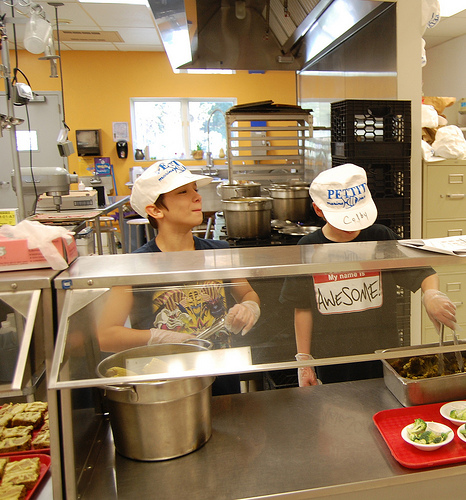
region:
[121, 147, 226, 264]
woman wears a white cap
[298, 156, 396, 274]
woman wears a white cap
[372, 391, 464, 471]
a red tray on a counter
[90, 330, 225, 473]
a pot color silver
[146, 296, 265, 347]
a pair of gloves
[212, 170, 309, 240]
pots over a stove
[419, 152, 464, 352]
a cabinet color beige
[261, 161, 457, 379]
woman wears a black top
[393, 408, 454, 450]
a white bowl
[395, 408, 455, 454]
a bowl with broccoli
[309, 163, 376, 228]
a white cap of the business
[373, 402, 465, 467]
a red cafeteria tray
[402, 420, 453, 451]
a bowl of broccoli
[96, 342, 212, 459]
a stainless steel pot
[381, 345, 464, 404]
a stainless steel pan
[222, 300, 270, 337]
a clear sanitary serving glove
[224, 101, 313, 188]
a metal tray cart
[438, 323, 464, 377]
metal kitchen serving tongs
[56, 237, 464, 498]
a metal food display case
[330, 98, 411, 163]
brown plastic milk container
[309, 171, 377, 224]
Cap in the photo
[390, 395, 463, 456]
Plates on the table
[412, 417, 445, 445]
lemons on the plate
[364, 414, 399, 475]
Red tray in the photo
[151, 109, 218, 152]
Window on the building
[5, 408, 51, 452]
Bread on the tray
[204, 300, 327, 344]
Glass on the shelf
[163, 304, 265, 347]
Gloves on the hands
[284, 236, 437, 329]
Black t-shirt in the photo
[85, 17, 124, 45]
Ceiling on the photo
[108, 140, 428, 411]
two kids working in a soup kitchen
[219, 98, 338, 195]
a baker's rack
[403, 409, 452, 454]
broccoli in a dish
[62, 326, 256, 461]
a pot of food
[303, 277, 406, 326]
this boy says his name is awesome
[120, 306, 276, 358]
the boy is wearing protective gloves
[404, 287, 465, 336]
this boy is wearing gloves as well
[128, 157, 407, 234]
both kids are wearing white hats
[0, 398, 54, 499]
pastrys set to the left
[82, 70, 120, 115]
the wall is yellow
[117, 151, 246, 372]
this is a person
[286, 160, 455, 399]
this is a person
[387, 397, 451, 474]
a plate of food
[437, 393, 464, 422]
a plate of food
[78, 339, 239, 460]
this is a cooking pot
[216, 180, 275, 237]
this is a cooking pot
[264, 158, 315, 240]
this is a cooking pot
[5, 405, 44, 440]
this is a loaf of bread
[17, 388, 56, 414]
this is a loaf of bread